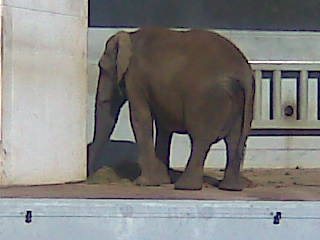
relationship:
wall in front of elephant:
[27, 206, 263, 232] [91, 17, 259, 191]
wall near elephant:
[0, 8, 91, 189] [91, 17, 259, 191]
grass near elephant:
[95, 163, 124, 184] [91, 17, 259, 191]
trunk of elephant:
[86, 71, 124, 170] [91, 17, 259, 191]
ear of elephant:
[115, 30, 131, 83] [91, 17, 259, 191]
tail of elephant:
[236, 72, 253, 162] [91, 17, 259, 191]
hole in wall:
[283, 105, 293, 115] [88, 26, 317, 166]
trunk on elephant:
[86, 68, 127, 178] [91, 17, 259, 191]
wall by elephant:
[3, 3, 91, 185] [91, 17, 259, 191]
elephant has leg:
[91, 17, 259, 191] [129, 107, 170, 185]